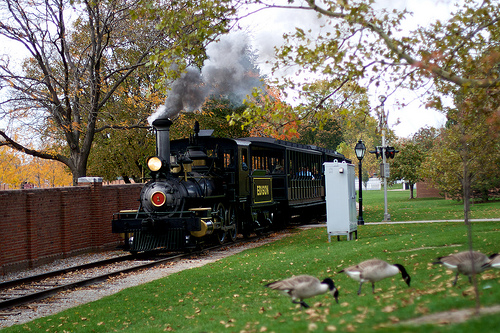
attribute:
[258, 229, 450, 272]
space — green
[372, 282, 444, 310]
leaves — brown , dead leaves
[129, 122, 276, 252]
engine — old, steam powered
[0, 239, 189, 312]
track — train track , on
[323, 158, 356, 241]
electrical box — tall, gray